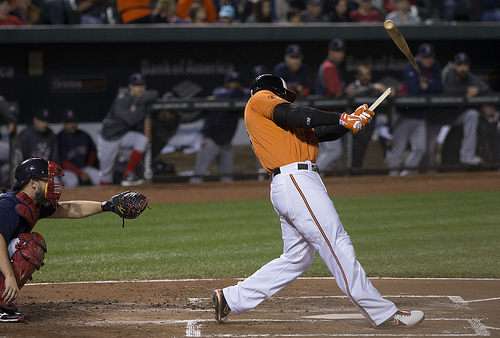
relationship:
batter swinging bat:
[195, 66, 425, 336] [379, 9, 434, 92]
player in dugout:
[431, 52, 498, 169] [2, 20, 492, 191]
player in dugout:
[388, 40, 444, 172] [2, 20, 492, 191]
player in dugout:
[350, 66, 392, 161] [2, 20, 492, 191]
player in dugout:
[316, 36, 363, 170] [2, 20, 492, 191]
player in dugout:
[191, 65, 260, 186] [2, 20, 492, 191]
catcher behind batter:
[82, 180, 174, 238] [236, 60, 433, 284]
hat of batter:
[249, 73, 293, 98] [212, 71, 426, 327]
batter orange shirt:
[212, 71, 426, 327] [243, 89, 320, 173]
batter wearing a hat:
[212, 71, 426, 327] [249, 73, 293, 98]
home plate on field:
[301, 310, 366, 321] [152, 187, 488, 287]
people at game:
[1, 1, 498, 28] [61, 63, 448, 333]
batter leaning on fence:
[212, 71, 426, 327] [103, 92, 241, 172]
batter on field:
[212, 71, 426, 327] [1, 171, 498, 336]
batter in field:
[212, 71, 426, 327] [1, 171, 498, 336]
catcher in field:
[1, 156, 151, 324] [1, 171, 498, 336]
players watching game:
[11, 4, 486, 172] [36, 45, 477, 334]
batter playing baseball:
[212, 71, 426, 327] [0, 27, 498, 336]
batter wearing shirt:
[212, 71, 426, 327] [241, 87, 340, 171]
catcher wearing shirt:
[1, 156, 151, 324] [241, 87, 340, 171]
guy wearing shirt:
[97, 73, 157, 188] [241, 87, 340, 171]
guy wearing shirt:
[57, 107, 99, 184] [241, 87, 340, 171]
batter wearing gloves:
[212, 71, 426, 327] [330, 101, 387, 148]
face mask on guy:
[47, 160, 64, 209] [2, 155, 158, 325]